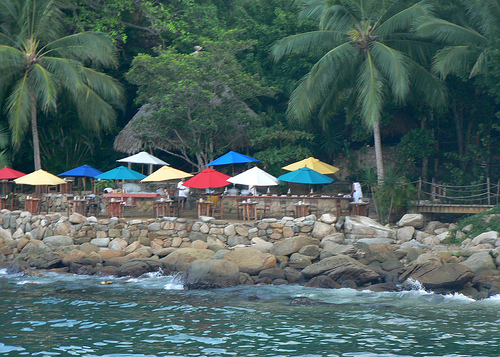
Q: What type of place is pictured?
A: It is an ocean.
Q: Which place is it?
A: It is an ocean.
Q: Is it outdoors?
A: Yes, it is outdoors.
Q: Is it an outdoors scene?
A: Yes, it is outdoors.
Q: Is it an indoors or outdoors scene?
A: It is outdoors.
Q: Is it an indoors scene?
A: No, it is outdoors.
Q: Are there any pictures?
A: No, there are no pictures.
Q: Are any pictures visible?
A: No, there are no pictures.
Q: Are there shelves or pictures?
A: No, there are no pictures or shelves.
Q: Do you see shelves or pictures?
A: No, there are no pictures or shelves.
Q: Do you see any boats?
A: No, there are no boats.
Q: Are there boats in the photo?
A: No, there are no boats.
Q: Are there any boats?
A: No, there are no boats.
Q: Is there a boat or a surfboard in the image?
A: No, there are no boats or surfboards.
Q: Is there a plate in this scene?
A: No, there are no plates.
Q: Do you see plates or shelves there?
A: No, there are no plates or shelves.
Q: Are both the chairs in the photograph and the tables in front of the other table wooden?
A: Yes, both the chairs and the tables are wooden.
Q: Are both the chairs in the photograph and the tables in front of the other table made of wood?
A: Yes, both the chairs and the tables are made of wood.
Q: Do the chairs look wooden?
A: Yes, the chairs are wooden.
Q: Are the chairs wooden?
A: Yes, the chairs are wooden.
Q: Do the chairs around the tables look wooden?
A: Yes, the chairs are wooden.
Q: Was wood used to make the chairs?
A: Yes, the chairs are made of wood.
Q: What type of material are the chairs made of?
A: The chairs are made of wood.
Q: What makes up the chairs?
A: The chairs are made of wood.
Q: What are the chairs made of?
A: The chairs are made of wood.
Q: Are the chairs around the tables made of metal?
A: No, the chairs are made of wood.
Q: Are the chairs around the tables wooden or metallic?
A: The chairs are wooden.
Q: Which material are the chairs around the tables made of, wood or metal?
A: The chairs are made of wood.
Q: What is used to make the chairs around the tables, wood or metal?
A: The chairs are made of wood.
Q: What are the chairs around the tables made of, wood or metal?
A: The chairs are made of wood.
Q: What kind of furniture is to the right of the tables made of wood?
A: The pieces of furniture are chairs.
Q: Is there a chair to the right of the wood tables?
A: Yes, there are chairs to the right of the tables.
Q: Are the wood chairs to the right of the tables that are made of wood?
A: Yes, the chairs are to the right of the tables.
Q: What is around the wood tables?
A: The chairs are around the tables.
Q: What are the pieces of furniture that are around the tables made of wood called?
A: The pieces of furniture are chairs.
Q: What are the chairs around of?
A: The chairs are around the tables.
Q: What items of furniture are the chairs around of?
A: The chairs are around the tables.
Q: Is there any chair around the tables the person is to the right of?
A: Yes, there are chairs around the tables.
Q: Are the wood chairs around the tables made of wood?
A: Yes, the chairs are around the tables.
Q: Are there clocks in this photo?
A: No, there are no clocks.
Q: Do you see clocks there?
A: No, there are no clocks.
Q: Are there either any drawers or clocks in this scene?
A: No, there are no clocks or drawers.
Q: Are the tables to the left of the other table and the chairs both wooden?
A: Yes, both the tables and the chairs are wooden.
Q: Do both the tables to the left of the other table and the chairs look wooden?
A: Yes, both the tables and the chairs are wooden.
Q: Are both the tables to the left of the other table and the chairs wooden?
A: Yes, both the tables and the chairs are wooden.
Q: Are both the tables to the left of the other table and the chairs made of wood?
A: Yes, both the tables and the chairs are made of wood.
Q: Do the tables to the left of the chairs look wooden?
A: Yes, the tables are wooden.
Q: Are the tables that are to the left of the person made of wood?
A: Yes, the tables are made of wood.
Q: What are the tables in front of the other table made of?
A: The tables are made of wood.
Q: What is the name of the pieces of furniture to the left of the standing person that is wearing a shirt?
A: The pieces of furniture are tables.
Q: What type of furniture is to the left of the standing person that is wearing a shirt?
A: The pieces of furniture are tables.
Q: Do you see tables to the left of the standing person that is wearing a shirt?
A: Yes, there are tables to the left of the person.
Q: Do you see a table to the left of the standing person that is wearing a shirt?
A: Yes, there are tables to the left of the person.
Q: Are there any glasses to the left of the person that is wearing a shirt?
A: No, there are tables to the left of the person.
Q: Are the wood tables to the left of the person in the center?
A: Yes, the tables are to the left of the person.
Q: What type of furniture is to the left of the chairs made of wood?
A: The pieces of furniture are tables.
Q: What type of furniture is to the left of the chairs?
A: The pieces of furniture are tables.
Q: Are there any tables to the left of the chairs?
A: Yes, there are tables to the left of the chairs.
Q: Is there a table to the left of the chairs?
A: Yes, there are tables to the left of the chairs.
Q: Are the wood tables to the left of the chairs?
A: Yes, the tables are to the left of the chairs.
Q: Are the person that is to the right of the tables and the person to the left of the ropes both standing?
A: Yes, both the person and the person are standing.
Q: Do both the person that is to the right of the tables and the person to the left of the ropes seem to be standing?
A: Yes, both the person and the person are standing.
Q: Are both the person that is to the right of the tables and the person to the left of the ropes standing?
A: Yes, both the person and the person are standing.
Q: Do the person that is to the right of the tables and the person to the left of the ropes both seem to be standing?
A: Yes, both the person and the person are standing.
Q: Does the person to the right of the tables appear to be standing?
A: Yes, the person is standing.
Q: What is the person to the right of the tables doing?
A: The person is standing.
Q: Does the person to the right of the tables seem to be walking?
A: No, the person is standing.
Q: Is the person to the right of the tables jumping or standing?
A: The person is standing.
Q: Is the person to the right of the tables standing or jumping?
A: The person is standing.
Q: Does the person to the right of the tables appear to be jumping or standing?
A: The person is standing.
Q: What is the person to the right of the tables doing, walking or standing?
A: The person is standing.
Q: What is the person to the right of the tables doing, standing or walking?
A: The person is standing.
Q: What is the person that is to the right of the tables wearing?
A: The person is wearing a shirt.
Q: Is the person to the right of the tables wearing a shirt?
A: Yes, the person is wearing a shirt.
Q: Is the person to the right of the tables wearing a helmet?
A: No, the person is wearing a shirt.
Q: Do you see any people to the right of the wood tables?
A: Yes, there is a person to the right of the tables.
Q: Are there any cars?
A: No, there are no cars.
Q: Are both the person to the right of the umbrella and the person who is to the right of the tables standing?
A: Yes, both the person and the person are standing.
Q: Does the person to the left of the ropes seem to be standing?
A: Yes, the person is standing.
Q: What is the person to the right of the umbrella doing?
A: The person is standing.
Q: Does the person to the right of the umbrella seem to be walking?
A: No, the person is standing.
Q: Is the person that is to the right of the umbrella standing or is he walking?
A: The person is standing.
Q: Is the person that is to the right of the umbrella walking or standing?
A: The person is standing.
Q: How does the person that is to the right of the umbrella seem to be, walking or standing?
A: The person is standing.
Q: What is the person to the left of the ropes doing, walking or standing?
A: The person is standing.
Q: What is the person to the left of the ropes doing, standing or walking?
A: The person is standing.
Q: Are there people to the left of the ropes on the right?
A: Yes, there is a person to the left of the ropes.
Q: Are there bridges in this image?
A: Yes, there is a bridge.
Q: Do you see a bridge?
A: Yes, there is a bridge.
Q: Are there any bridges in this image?
A: Yes, there is a bridge.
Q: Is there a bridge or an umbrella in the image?
A: Yes, there is a bridge.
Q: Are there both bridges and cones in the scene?
A: No, there is a bridge but no cones.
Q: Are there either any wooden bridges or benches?
A: Yes, there is a wood bridge.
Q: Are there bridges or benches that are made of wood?
A: Yes, the bridge is made of wood.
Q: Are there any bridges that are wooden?
A: Yes, there is a bridge that is wooden.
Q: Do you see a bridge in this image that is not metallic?
A: Yes, there is a wooden bridge.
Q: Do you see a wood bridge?
A: Yes, there is a bridge that is made of wood.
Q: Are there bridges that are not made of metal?
A: Yes, there is a bridge that is made of wood.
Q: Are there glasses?
A: No, there are no glasses.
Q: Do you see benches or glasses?
A: No, there are no glasses or benches.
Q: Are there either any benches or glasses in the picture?
A: No, there are no glasses or benches.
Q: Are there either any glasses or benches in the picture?
A: No, there are no glasses or benches.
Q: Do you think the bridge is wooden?
A: Yes, the bridge is wooden.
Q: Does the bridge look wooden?
A: Yes, the bridge is wooden.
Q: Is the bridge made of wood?
A: Yes, the bridge is made of wood.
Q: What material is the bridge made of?
A: The bridge is made of wood.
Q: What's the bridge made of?
A: The bridge is made of wood.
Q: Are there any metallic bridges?
A: No, there is a bridge but it is wooden.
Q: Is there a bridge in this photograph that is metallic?
A: No, there is a bridge but it is wooden.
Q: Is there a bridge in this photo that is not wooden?
A: No, there is a bridge but it is wooden.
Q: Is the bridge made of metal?
A: No, the bridge is made of wood.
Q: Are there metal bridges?
A: No, there is a bridge but it is made of wood.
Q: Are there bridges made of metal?
A: No, there is a bridge but it is made of wood.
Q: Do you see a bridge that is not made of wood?
A: No, there is a bridge but it is made of wood.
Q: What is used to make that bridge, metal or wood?
A: The bridge is made of wood.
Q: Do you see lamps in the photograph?
A: No, there are no lamps.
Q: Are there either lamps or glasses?
A: No, there are no lamps or glasses.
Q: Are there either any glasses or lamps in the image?
A: No, there are no lamps or glasses.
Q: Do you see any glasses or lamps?
A: No, there are no lamps or glasses.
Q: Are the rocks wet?
A: Yes, the rocks are wet.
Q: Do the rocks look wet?
A: Yes, the rocks are wet.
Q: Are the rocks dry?
A: No, the rocks are wet.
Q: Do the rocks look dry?
A: No, the rocks are wet.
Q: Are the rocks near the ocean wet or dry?
A: The rocks are wet.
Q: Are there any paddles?
A: No, there are no paddles.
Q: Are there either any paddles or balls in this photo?
A: No, there are no paddles or balls.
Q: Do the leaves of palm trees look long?
A: Yes, the leaves are long.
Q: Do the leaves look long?
A: Yes, the leaves are long.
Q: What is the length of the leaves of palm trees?
A: The leaves are long.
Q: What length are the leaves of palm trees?
A: The leaves are long.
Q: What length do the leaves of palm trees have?
A: The leaves have long length.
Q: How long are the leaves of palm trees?
A: The leaves are long.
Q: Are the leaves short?
A: No, the leaves are long.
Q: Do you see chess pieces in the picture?
A: No, there are no chess pieces.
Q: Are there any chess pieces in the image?
A: No, there are no chess pieces.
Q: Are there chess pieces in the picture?
A: No, there are no chess pieces.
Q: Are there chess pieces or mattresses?
A: No, there are no chess pieces or mattresses.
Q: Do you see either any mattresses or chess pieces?
A: No, there are no chess pieces or mattresses.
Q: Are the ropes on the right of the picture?
A: Yes, the ropes are on the right of the image.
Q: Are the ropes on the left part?
A: No, the ropes are on the right of the image.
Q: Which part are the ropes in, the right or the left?
A: The ropes are on the right of the image.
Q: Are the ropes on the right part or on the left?
A: The ropes are on the right of the image.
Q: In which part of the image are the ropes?
A: The ropes are on the right of the image.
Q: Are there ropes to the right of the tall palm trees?
A: Yes, there are ropes to the right of the palms.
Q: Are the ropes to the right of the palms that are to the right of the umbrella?
A: Yes, the ropes are to the right of the palms.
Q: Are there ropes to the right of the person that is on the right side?
A: Yes, there are ropes to the right of the person.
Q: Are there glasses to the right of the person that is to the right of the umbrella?
A: No, there are ropes to the right of the person.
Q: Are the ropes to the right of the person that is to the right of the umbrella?
A: Yes, the ropes are to the right of the person.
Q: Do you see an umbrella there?
A: Yes, there is an umbrella.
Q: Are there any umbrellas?
A: Yes, there is an umbrella.